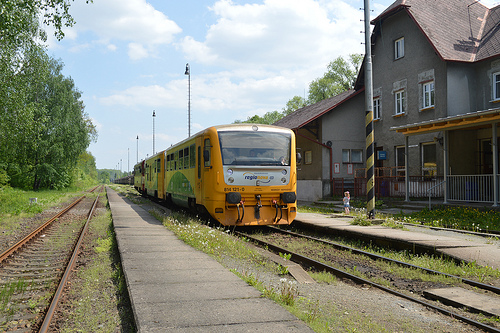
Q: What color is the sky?
A: Blue.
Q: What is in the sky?
A: Clouds.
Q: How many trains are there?
A: One.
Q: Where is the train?
A: On the tracks.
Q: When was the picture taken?
A: Daytime.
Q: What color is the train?
A: Yellow.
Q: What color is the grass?
A: Green.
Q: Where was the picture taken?
A: A train terminal.